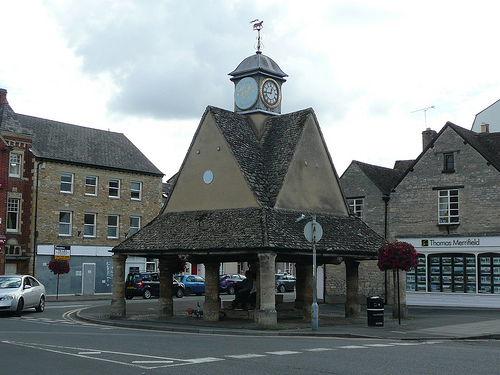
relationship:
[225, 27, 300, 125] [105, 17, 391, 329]
clock on building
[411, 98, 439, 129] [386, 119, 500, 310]
antenna on brick building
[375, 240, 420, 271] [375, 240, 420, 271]
flowers on flowers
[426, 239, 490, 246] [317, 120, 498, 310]
sign on building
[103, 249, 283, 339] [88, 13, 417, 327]
columns holding up building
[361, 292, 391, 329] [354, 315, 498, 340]
can near sidewalk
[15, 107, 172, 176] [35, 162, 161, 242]
roof on brick building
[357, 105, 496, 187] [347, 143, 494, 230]
roof on brick building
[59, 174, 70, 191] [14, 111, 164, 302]
window on building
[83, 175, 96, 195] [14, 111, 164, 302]
window on building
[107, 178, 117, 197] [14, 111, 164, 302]
window on building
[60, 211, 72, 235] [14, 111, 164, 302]
window on building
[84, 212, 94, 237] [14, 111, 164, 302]
window on building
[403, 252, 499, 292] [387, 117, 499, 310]
window on shop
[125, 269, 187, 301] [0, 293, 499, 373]
car on road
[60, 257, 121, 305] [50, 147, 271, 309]
door in brown building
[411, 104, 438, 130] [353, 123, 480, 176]
antenna atop a roof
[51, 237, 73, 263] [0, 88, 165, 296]
sign on a brick building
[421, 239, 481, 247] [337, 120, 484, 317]
sign on a building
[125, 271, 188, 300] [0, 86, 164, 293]
car in front of a building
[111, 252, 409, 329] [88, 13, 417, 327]
columns on a building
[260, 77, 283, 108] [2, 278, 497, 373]
clock in middle of a roundabout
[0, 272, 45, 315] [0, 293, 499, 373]
car rounding road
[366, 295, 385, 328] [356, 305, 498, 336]
can near corner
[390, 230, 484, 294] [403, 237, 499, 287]
storefront with photos in windows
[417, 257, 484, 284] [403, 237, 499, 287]
photos in windows